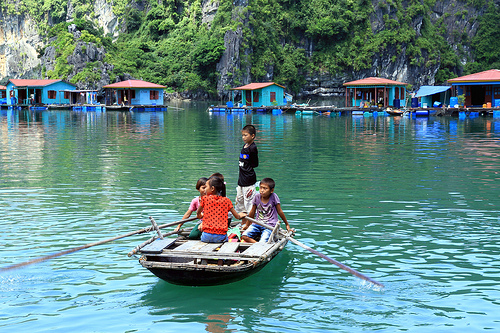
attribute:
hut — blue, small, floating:
[230, 80, 286, 107]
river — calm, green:
[1, 97, 499, 332]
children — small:
[174, 124, 291, 244]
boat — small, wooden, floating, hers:
[128, 219, 297, 286]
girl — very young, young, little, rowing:
[197, 178, 250, 245]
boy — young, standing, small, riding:
[235, 124, 258, 226]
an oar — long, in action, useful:
[245, 216, 385, 289]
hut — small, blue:
[5, 77, 78, 107]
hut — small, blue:
[102, 79, 166, 109]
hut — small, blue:
[342, 77, 407, 110]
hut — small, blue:
[414, 85, 453, 115]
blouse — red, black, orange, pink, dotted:
[198, 194, 234, 235]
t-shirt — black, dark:
[238, 141, 259, 187]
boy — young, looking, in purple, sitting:
[240, 178, 291, 244]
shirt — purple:
[252, 192, 280, 227]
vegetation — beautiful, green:
[1, 1, 500, 97]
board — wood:
[140, 237, 176, 253]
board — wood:
[171, 239, 210, 253]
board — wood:
[196, 236, 224, 253]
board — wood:
[217, 241, 239, 253]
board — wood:
[241, 241, 275, 256]